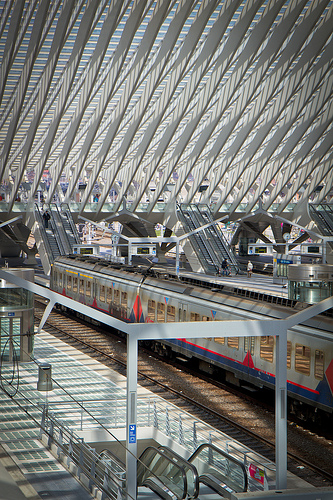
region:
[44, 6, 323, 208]
lots of long steel beams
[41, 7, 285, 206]
sun light coming between the steel beams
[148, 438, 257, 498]
escalator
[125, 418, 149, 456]
white arrow pointing down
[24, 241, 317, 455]
train stop passenger boarding area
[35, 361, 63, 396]
metal trash can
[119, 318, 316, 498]
two tall steel supporting structures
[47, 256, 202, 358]
silver, red, and blue passenger train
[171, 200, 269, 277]
person coming down an escalator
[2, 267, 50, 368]
steal elevator with door windows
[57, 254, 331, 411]
a red, white, and blue train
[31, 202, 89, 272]
an escalator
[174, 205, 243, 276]
an escalator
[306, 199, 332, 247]
an escalator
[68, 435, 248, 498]
an escalator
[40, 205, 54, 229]
a person on an escalator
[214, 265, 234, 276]
orange and white pylons in front of an escalator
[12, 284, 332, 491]
a set of train tracks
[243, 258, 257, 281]
a person in white in front of an escalator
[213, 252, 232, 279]
a person at the base of an escalator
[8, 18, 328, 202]
Architectural element in building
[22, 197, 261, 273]
Escalator in train station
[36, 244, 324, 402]
Grey, red and blue train at station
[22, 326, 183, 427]
Platform at train station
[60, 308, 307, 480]
Empty train tracks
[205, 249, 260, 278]
People walking through train station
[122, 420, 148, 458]
Directional signs indicating where people should go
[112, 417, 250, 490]
Escalator on the platform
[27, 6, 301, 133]
Blue sky showing through architectual element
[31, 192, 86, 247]
Person coming down escalator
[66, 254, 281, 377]
grey commuter train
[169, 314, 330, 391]
red and blue stripe on train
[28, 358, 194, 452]
white platform near train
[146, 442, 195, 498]
black handrail on escalator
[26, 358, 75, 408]
grey trash bin on platform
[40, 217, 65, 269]
grey steps on escalator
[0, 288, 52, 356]
metallic doors near platform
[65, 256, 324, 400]
train has multiple cars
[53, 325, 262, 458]
brown tracks beneath train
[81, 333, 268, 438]
gravel next to train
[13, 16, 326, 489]
This is a subway stop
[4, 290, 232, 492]
There are no people on the platform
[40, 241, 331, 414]
The train is silver, red, and blue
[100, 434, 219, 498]
There is an escalator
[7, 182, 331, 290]
There are three escalators in the background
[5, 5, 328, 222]
There is an interesting ceiling structure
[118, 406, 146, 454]
There is a blue down sign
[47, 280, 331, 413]
There is a blue and red stripe on the subway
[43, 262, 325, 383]
There are red triangles on the train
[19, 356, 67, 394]
There is a trash can